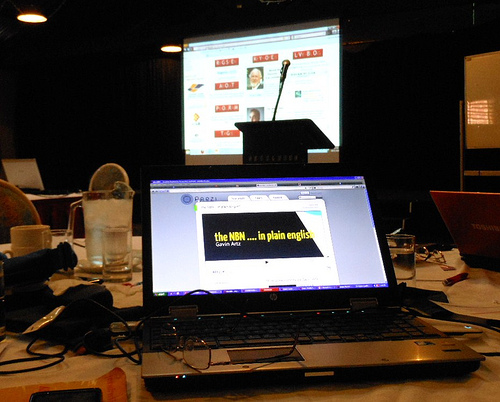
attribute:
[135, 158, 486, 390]
laptop — open, black, gray, on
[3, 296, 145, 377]
cord — black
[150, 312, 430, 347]
keys — black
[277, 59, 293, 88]
microphone — black, silver, metal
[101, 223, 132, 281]
glass — clear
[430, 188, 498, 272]
laptop — red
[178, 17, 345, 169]
projection screen — on, large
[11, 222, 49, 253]
mug — yellow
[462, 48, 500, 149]
board — white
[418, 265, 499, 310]
paper — white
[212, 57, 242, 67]
symbol — red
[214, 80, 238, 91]
symbol — red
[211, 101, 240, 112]
symbol — red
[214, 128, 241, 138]
symbol — red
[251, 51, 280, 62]
symbol — red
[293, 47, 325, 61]
symbol — red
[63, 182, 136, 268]
water pitcher — glass